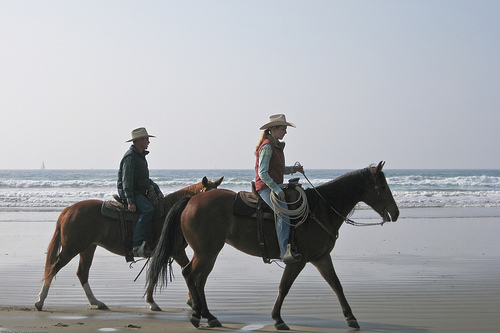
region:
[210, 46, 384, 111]
The sky is blue.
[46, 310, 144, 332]
Footprints in the sand.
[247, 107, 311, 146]
Hat on the woman's head.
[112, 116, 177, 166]
Hat on the man's head.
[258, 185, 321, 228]
Rope on the lap.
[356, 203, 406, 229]
The mouth is slightly open.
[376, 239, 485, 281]
The sand is wet.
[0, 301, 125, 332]
The sand is brown.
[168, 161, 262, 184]
The water is blue.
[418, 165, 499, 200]
White foam in the water.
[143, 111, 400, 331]
woman riding a horse on the beach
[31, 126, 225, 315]
man riding a horse on the beach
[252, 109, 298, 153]
woman in a cowboy hat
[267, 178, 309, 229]
lasso attached to saddle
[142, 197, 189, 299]
long black hair of tail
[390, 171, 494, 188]
white caps on waves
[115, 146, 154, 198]
man wearing a green vest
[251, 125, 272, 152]
blonde ponytail on woman's head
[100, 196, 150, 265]
beige leather saddle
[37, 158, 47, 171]
sailboat in far distance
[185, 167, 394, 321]
brown horse ridden on beach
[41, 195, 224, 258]
brown horse ridden on beach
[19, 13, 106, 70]
white clouds in blue sky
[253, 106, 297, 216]
woman riding brown horse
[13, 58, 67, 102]
white clouds in blue sky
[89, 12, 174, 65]
white clouds in blue sky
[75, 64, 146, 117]
white clouds in blue sky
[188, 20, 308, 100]
white clouds in blue sky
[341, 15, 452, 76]
white clouds in blue sky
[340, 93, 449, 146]
white clouds in blue sky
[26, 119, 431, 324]
two people riding horses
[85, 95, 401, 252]
a man and a woman riding horses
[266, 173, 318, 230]
a rope on a saddle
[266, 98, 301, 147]
a woman wearing a hat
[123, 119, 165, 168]
a man wearing a cowboy hat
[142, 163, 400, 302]
a horse with a black tail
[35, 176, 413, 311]
two horses walking on a beach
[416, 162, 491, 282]
a beach by the ocean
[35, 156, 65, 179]
a boat in the ocean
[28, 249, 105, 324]
a horse with two white feet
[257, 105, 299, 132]
hat worn by young woman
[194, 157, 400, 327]
brown horse ridden by young woman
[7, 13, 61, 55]
white clouds in blue sky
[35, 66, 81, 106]
white clouds in blue sky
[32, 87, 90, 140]
white clouds in blue sky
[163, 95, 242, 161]
white clouds in blue sky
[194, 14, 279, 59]
white clouds in blue sky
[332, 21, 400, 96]
white clouds in blue sky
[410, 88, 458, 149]
white clouds in blue sky